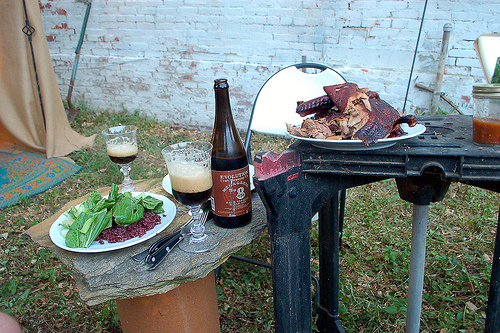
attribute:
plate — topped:
[285, 121, 431, 152]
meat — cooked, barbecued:
[288, 80, 428, 136]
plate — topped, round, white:
[49, 186, 177, 258]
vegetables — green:
[60, 178, 166, 247]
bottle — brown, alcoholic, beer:
[203, 75, 257, 234]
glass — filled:
[158, 134, 233, 263]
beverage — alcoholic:
[171, 173, 217, 205]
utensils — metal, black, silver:
[130, 201, 212, 275]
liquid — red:
[475, 113, 500, 141]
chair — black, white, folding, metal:
[237, 58, 350, 211]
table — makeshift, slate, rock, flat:
[25, 168, 275, 309]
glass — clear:
[99, 121, 151, 193]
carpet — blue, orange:
[0, 143, 87, 207]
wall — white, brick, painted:
[40, 2, 498, 137]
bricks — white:
[148, 9, 198, 30]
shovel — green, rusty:
[59, 0, 100, 130]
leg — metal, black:
[264, 205, 323, 333]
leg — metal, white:
[403, 209, 441, 332]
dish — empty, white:
[154, 173, 176, 198]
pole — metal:
[430, 18, 456, 115]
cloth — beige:
[2, 1, 88, 153]